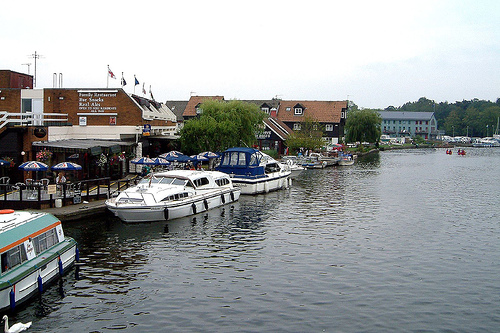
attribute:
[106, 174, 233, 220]
boat — white, orange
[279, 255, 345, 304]
water — green, calm, black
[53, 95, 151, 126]
building — brick, brown